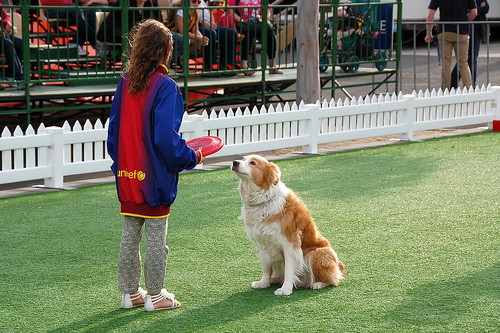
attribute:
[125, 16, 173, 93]
hair — windblown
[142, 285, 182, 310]
sandal — white, strappy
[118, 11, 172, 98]
hair — girl's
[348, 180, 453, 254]
turf — green, grassy, astro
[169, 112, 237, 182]
frisbee — red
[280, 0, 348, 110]
post — thick, wooden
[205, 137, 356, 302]
dog — black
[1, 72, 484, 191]
fence — low, white, picket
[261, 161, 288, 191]
ear — brown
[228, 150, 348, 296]
dog — sitting, brown, white, long haired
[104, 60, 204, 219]
jacket — too big